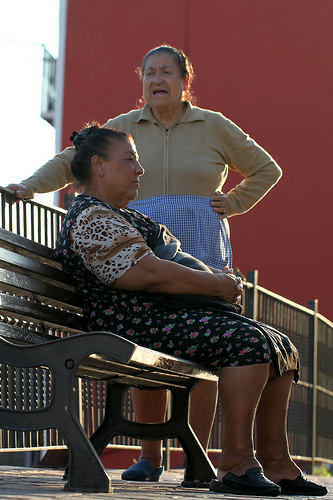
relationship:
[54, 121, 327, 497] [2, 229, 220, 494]
women sitting on bench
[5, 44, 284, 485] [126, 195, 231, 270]
woman wearing apron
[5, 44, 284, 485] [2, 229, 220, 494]
woman next to bench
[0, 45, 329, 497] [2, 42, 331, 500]
women at bus stop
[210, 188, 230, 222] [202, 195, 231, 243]
hand on hip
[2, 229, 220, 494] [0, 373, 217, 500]
bench has legs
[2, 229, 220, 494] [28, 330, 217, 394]
bench has seat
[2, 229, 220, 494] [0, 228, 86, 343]
bench has back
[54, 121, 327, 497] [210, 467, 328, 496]
women wearing shoes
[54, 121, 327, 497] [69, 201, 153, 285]
women wearing shirt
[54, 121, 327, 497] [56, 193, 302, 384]
women wearing dress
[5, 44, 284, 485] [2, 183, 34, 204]
woman has hand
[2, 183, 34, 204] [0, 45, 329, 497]
hand on railing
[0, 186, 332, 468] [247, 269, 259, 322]
fence has post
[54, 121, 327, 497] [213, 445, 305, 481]
women has ankles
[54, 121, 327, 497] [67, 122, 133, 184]
women has hair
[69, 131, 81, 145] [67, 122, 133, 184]
clip in hair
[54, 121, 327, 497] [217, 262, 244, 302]
women has hands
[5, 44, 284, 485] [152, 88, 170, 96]
woman has mouth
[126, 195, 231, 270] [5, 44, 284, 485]
apron on woman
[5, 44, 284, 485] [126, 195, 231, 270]
woman has apron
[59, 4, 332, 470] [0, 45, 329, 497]
wall behind women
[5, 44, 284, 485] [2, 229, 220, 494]
woman standing near bench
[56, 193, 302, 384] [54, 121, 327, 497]
dress on women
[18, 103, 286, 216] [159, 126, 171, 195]
dress has zipper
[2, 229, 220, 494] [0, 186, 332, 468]
bench near fence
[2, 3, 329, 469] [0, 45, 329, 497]
building behind women